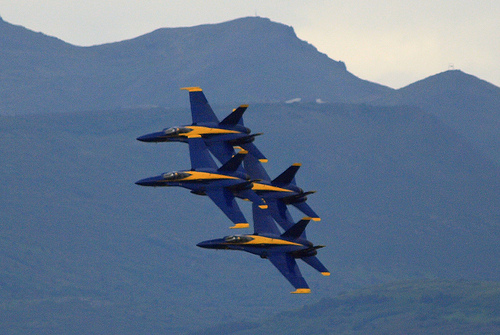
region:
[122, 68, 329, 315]
blue and yellow jets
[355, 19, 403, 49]
white clouds in blue sky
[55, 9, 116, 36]
white clouds in blue sky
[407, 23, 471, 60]
white clouds in blue sky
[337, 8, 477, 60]
white clouds in blue sky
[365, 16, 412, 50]
white clouds in blue sky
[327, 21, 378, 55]
white clouds in blue sky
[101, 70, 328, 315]
blue and gold planes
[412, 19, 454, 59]
white clouds in blue sky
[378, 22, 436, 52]
white clouds in blue sky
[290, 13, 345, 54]
white clouds in blue sky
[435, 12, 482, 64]
white clouds in blue sky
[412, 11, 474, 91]
white clouds in blue sky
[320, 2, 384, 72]
white clouds in blue sky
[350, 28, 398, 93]
white clouds in blue sky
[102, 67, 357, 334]
four planes in the air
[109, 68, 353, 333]
four planes in formation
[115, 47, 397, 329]
four blue and yellow planes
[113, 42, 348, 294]
four planes together in the air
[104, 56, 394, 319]
four planes in the sky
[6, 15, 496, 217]
a mountain in the background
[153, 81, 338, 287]
yellow on the top of planes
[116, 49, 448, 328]
four planes flying too close together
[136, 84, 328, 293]
5 planes in formation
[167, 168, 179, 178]
the cockpit of a plane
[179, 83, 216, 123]
the left wing of a plane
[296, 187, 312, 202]
the tail fin of a plane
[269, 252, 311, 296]
the left wing of a plane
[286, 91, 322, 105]
a white paved road in the mountains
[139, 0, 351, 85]
the hump of a mountain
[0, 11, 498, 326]
a grassy mountain range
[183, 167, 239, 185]
a yellow streak on the back of a plane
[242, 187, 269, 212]
the back end of a plane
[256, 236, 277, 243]
the body is yellow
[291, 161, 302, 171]
the tip of the tail is yellow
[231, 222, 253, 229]
the tip of the wing is yellow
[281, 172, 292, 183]
the tail is blue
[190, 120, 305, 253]
the jets are flying together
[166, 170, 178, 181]
the glass is clear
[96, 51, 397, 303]
planes in the air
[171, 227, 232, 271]
front of the plane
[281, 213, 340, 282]
back wing of plane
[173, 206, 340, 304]
blue and yellow plane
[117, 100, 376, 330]
many planes in a group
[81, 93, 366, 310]
planes flying in formation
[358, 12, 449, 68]
sky above the mountains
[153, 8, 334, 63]
top of the hill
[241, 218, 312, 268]
yellow strip in plane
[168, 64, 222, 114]
edge of the wing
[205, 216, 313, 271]
an airplane in the air